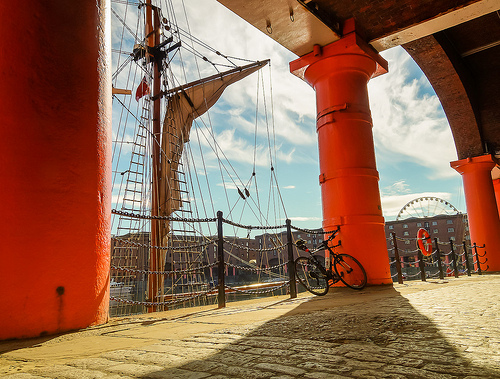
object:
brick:
[338, 339, 391, 354]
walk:
[7, 270, 498, 372]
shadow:
[135, 287, 499, 377]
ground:
[1, 271, 499, 377]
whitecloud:
[371, 80, 441, 167]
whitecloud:
[115, 31, 303, 174]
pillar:
[301, 53, 393, 285]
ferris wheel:
[388, 196, 474, 278]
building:
[5, 0, 499, 379]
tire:
[332, 253, 369, 290]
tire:
[293, 253, 331, 296]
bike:
[286, 224, 373, 298]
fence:
[111, 205, 336, 292]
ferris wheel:
[396, 195, 460, 220]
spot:
[55, 284, 65, 298]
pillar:
[0, 0, 112, 341]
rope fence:
[111, 208, 489, 318]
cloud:
[112, 2, 479, 206]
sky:
[101, 0, 498, 250]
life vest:
[412, 224, 437, 258]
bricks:
[206, 359, 279, 378]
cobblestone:
[279, 327, 292, 337]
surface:
[155, 304, 489, 355]